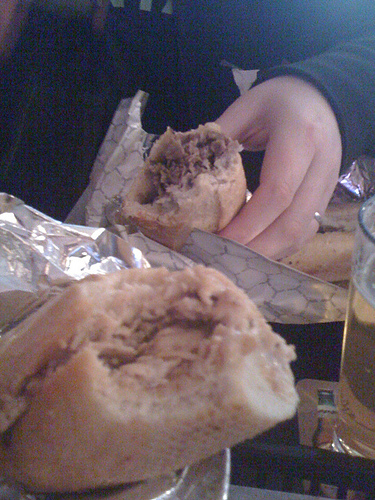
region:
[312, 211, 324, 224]
ring on finger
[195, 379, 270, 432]
white bread thats bene bitten into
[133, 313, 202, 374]
source of protein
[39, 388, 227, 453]
high source of carbs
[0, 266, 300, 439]
sandwich thats been bitten into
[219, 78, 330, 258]
hand of caucasian human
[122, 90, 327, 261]
hand grabbing sandwich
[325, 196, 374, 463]
cup with golden liquid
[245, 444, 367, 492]
basket of some sort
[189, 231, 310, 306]
foil for holding food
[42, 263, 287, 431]
sandwich has been bitten into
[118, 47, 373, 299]
person holding a sandwich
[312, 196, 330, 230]
person wearing a ring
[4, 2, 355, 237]
person's shirt is black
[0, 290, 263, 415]
meat inside the sandwich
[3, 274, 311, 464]
sandwich bread is brown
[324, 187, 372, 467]
glass cup near the sandwich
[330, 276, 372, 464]
brown liquid in the cup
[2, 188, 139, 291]
aluminum wrapper is silver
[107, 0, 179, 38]
letters on person's shirt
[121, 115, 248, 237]
beef sandwich in the man's hand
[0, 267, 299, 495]
an already bit into sandwich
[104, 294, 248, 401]
meat on the inside of the sandwich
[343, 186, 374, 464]
glass of beer on the table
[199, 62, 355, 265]
person's left hand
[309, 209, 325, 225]
ring on the person's left finger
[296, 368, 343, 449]
coaster under the beer mug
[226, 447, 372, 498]
basket holding the sandwich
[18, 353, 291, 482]
bun of the sandwich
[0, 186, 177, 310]
wrapper for the sandwich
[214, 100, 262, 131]
THAT IS A FINGER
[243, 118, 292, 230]
THAT IS A FINGER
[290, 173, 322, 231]
THAT IS A FINGER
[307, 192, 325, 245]
THAT IS A FINGER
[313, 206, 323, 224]
A RING ON THE FINGER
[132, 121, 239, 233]
THAT IS A HUMBERGER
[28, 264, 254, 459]
THAT IS A HUMBERGER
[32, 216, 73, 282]
THAT IS FOIL PARPER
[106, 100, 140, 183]
THAT IS FOIL PARPER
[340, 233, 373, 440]
THAT IS A GLASS OF JUICE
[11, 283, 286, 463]
The sandwich has been eaten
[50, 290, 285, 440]
holding a meat sandwich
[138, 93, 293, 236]
another sandwich being eaten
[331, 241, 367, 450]
A glass of yellow liquid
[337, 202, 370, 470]
A tall clear glass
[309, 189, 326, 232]
The person has a ring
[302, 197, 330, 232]
the ring is silver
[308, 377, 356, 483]
picture of a beer bottle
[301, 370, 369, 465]
the glass sits on a coaster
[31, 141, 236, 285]
sandwich wrapped in a wrapper